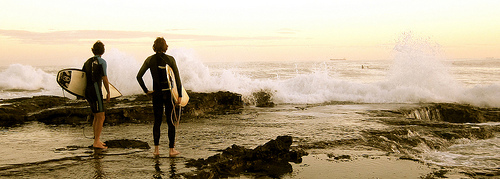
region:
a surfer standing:
[141, 35, 193, 160]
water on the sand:
[288, 107, 342, 132]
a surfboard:
[47, 67, 82, 91]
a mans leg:
[87, 112, 108, 145]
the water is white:
[298, 75, 350, 100]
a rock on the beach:
[220, 131, 295, 173]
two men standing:
[74, 37, 189, 159]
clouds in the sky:
[185, 29, 262, 44]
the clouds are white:
[15, 24, 85, 46]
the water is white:
[417, 140, 496, 165]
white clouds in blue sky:
[20, 41, 65, 68]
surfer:
[36, 35, 122, 145]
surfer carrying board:
[116, 35, 182, 141]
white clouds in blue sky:
[415, 7, 458, 47]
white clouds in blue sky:
[333, 20, 374, 56]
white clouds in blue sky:
[277, 30, 347, 77]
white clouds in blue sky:
[210, 27, 266, 92]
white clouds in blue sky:
[395, 50, 440, 80]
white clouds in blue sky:
[302, 45, 374, 93]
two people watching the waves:
[42, 11, 199, 157]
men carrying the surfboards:
[52, 37, 209, 174]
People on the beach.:
[57, 35, 278, 174]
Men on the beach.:
[43, 36, 232, 176]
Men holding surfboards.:
[47, 33, 267, 163]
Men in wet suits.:
[43, 44, 263, 170]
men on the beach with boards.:
[36, 27, 292, 165]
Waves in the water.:
[253, 49, 403, 142]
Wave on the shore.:
[198, 57, 449, 174]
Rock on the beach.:
[196, 127, 213, 160]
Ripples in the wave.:
[281, 92, 436, 176]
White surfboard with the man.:
[34, 46, 132, 120]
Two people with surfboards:
[52, 33, 183, 161]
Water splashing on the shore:
[3, 29, 498, 107]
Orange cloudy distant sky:
[3, 1, 497, 61]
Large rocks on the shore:
[3, 86, 310, 176]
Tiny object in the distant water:
[358, 59, 368, 72]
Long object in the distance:
[327, 53, 349, 64]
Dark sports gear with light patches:
[75, 55, 112, 110]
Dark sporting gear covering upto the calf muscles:
[135, 49, 184, 145]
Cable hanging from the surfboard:
[165, 86, 186, 127]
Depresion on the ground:
[363, 94, 499, 177]